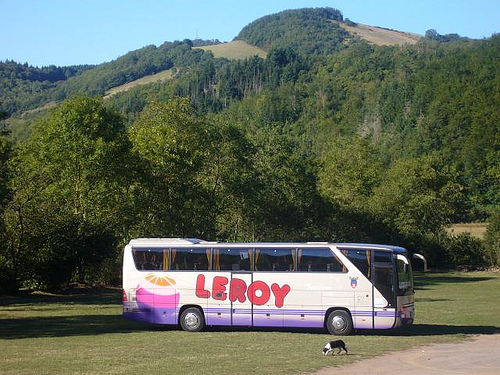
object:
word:
[192, 272, 294, 309]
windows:
[130, 237, 370, 282]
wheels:
[326, 309, 353, 336]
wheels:
[175, 304, 207, 331]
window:
[390, 250, 412, 293]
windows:
[296, 248, 348, 272]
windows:
[252, 247, 296, 271]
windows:
[211, 247, 251, 269]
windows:
[167, 248, 209, 268]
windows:
[132, 246, 169, 270]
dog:
[322, 339, 348, 356]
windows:
[283, 241, 347, 298]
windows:
[133, 241, 260, 288]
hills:
[227, 8, 500, 101]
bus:
[122, 237, 427, 336]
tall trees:
[13, 60, 478, 294]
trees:
[0, 9, 498, 297]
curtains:
[163, 248, 176, 271]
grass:
[2, 274, 498, 374]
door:
[374, 263, 396, 329]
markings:
[317, 345, 336, 351]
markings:
[325, 342, 332, 349]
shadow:
[27, 292, 77, 342]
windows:
[129, 244, 327, 270]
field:
[0, 271, 500, 375]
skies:
[44, 18, 154, 46]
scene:
[12, 22, 407, 219]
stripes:
[127, 302, 384, 330]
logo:
[195, 274, 291, 308]